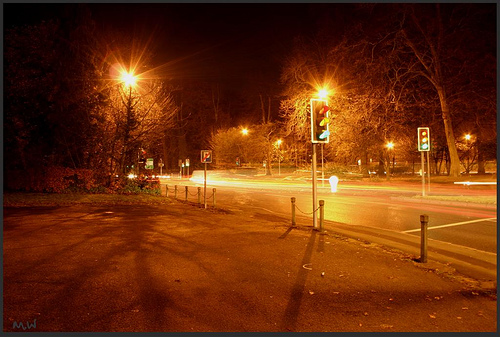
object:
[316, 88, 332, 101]
light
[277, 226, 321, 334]
shadow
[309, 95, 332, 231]
light post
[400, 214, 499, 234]
white line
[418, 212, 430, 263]
barrier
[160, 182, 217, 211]
fence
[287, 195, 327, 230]
fence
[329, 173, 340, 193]
light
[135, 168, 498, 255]
road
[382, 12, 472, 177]
tree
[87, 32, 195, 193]
tree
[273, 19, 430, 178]
tree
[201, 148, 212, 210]
sign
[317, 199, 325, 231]
barrier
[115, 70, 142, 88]
light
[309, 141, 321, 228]
pole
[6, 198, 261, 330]
shadow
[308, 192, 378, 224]
glare